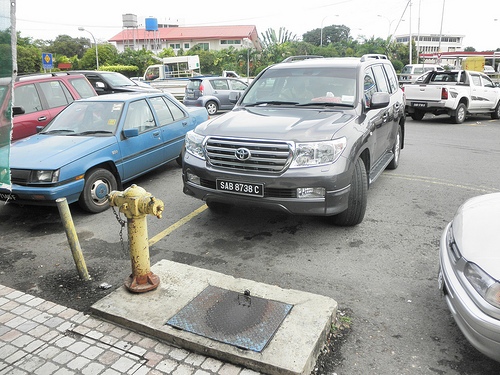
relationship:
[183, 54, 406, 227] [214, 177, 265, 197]
suv has license plate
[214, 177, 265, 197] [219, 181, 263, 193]
license plate has writing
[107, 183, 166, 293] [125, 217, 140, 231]
fire hydrant has rust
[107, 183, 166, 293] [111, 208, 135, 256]
hydrant has chain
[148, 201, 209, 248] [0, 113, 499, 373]
line painted on ground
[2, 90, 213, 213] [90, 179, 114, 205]
car has hubcap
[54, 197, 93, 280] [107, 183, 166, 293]
stop pole next to fire hydrant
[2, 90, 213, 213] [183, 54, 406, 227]
car next to suv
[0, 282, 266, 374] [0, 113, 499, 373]
sidewalk next to ground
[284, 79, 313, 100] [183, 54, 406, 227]
man inside of car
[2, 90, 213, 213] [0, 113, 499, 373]
car inside of parking lot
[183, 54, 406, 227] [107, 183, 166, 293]
suv behind fire hydrant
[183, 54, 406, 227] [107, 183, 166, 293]
suv next to fire hydrant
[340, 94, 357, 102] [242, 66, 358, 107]
sticker in front of windshield